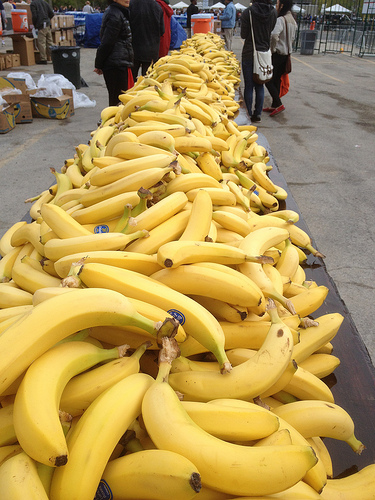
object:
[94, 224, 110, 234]
stickers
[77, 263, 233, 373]
banana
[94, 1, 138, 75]
coat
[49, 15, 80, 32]
boxes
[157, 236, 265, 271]
bananas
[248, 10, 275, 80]
bag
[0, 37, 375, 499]
table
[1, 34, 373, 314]
ground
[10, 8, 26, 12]
lid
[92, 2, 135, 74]
jacket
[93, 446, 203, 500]
bananas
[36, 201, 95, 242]
banana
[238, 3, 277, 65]
jacket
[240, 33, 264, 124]
jeans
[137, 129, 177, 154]
banana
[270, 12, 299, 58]
shirt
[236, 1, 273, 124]
standing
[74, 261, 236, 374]
single serve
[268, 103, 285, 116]
shoes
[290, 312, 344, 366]
bananas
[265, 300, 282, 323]
stem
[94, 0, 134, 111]
people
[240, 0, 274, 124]
person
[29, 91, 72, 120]
boxes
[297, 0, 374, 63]
fence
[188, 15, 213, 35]
cooler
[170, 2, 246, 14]
tents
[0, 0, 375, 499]
picture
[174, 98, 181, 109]
stalk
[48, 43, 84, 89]
can